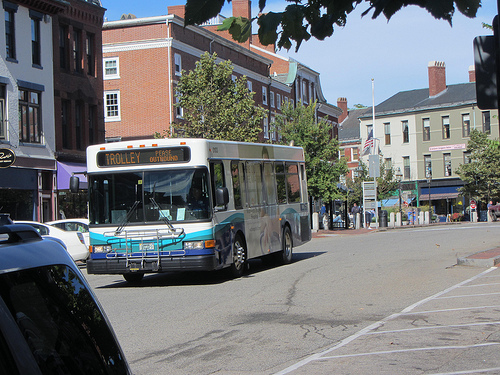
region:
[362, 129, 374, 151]
AMERICAN FLAG FLYING IN THE BACKGROUND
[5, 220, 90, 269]
WHITE CAR PARKED ON THE SIDE OF THE STREET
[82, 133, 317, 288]
BLUE AND WHITE PASSENGER BUS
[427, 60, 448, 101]
BRICK CHIMNEY ON THE ROOF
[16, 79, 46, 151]
EXTERIOR BUILDING WINDOW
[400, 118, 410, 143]
WINDOW WITH CURTAINS HUNG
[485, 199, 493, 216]
PERSON WEARING A BLUE SHIRT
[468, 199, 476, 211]
RED AND WHITE DO NOT ENTER SIGN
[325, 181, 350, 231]
BLACK BUS STOP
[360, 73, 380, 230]
WHITE FLAG POLE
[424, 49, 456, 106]
a red brick chimney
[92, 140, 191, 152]
five orange light's on top front of bus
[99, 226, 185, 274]
a metal bus rack on the front of the bus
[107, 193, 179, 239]
two black windshield wipers on the bus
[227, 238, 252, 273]
a silver hubcap that sticks out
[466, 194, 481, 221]
a white and red do not enter sign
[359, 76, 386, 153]
an american flag on a white pole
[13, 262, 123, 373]
reflection of tree leaf's in the car window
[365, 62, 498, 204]
a grey building with dark grey roof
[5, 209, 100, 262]
two white cars parked on the side of the street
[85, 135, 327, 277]
Trolly bus on the street.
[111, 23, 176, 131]
Building made of bricks.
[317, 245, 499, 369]
White parking lines on street.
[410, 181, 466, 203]
Blue awning over door.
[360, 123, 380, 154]
United States flag on pole.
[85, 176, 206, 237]
Black wipers on front of bus.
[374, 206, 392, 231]
Black barrel on sidewalk.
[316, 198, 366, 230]
People walking on the sidewalk.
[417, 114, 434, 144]
White shade in window.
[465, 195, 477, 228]
Stop sign in the back of the street.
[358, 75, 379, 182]
Flag at half mast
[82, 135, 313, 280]
On duty city bus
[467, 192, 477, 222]
Do not enter sign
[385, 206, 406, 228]
Poured concrete safety barricades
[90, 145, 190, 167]
City bus route sign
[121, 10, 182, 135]
Historic red brick building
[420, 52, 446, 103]
Large red brick chimney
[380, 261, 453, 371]
White no parking street lines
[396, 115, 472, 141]
Windows with shades and curtains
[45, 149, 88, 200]
Bright purple shop awning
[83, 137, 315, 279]
large bus on street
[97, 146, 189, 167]
LED display on bus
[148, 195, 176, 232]
black windshield wiper on windshield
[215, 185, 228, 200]
black side mirror on bus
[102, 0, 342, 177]
large red brick building behind bus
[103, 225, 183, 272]
gray metal bike rack on bus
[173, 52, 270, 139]
green tree behind bus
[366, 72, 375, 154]
flag on white flag pole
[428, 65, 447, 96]
red chimney on gray roof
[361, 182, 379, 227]
sign in front of flag pole